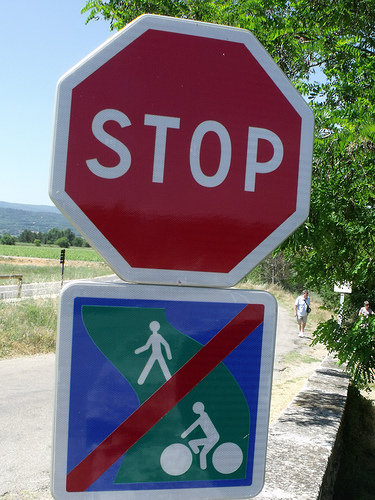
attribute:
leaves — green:
[302, 95, 373, 396]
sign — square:
[23, 46, 329, 253]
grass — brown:
[1, 300, 60, 353]